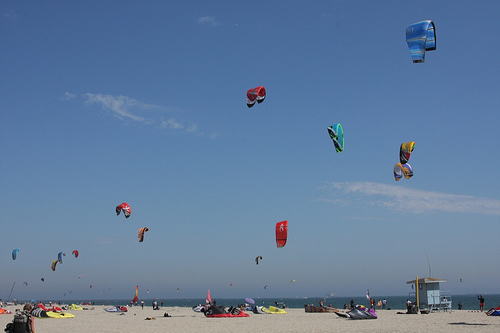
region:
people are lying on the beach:
[0, 275, 477, 331]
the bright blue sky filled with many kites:
[5, 3, 499, 296]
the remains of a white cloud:
[73, 82, 202, 139]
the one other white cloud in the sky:
[335, 180, 499, 230]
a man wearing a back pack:
[9, 300, 36, 330]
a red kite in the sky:
[269, 220, 293, 250]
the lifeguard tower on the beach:
[407, 270, 447, 320]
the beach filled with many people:
[3, 298, 498, 328]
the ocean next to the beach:
[157, 287, 494, 312]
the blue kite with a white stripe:
[403, 19, 441, 61]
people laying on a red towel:
[203, 302, 253, 319]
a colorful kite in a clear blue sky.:
[236, 71, 273, 117]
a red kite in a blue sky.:
[268, 214, 303, 253]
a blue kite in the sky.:
[319, 106, 349, 171]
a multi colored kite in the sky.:
[383, 129, 434, 192]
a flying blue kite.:
[388, 10, 460, 68]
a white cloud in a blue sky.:
[47, 68, 212, 145]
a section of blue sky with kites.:
[235, 13, 445, 255]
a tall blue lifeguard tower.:
[402, 257, 453, 320]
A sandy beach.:
[3, 303, 498, 332]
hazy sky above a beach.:
[4, 243, 496, 307]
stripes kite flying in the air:
[385, 22, 451, 69]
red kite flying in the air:
[265, 211, 305, 253]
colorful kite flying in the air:
[380, 130, 420, 180]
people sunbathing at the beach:
[15, 296, 426, 326]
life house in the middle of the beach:
[406, 265, 451, 320]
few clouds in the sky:
[70, 45, 216, 151]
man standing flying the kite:
[470, 285, 492, 315]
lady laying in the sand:
[22, 296, 78, 316]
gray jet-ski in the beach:
[340, 303, 385, 313]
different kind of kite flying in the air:
[0, 202, 332, 264]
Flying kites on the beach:
[0, 30, 446, 287]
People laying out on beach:
[4, 295, 397, 330]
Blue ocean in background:
[259, 288, 414, 308]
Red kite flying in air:
[251, 198, 294, 255]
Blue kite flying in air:
[386, 12, 449, 66]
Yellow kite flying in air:
[386, 137, 425, 187]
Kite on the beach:
[42, 306, 79, 324]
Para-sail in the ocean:
[127, 285, 141, 304]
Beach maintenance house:
[395, 268, 457, 315]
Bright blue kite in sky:
[318, 115, 351, 157]